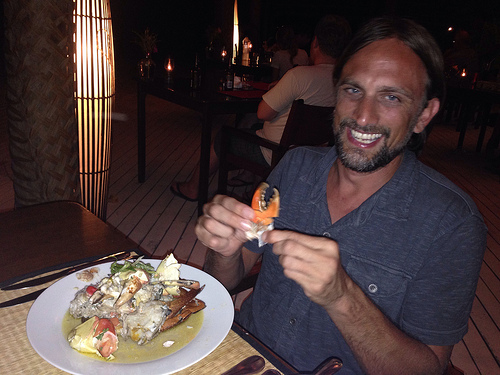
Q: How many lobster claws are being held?
A: One.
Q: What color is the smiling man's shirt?
A: Blue.